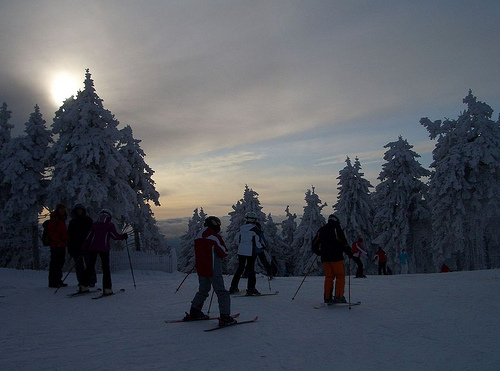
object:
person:
[305, 212, 364, 310]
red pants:
[320, 261, 347, 304]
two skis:
[314, 298, 364, 309]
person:
[180, 214, 240, 335]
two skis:
[165, 310, 258, 333]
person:
[70, 206, 139, 301]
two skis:
[67, 285, 126, 302]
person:
[227, 210, 282, 299]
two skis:
[227, 286, 280, 299]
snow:
[368, 276, 498, 371]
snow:
[33, 64, 147, 205]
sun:
[42, 69, 85, 107]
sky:
[145, 1, 375, 156]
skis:
[309, 301, 364, 310]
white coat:
[229, 222, 264, 257]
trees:
[287, 182, 331, 281]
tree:
[41, 67, 158, 273]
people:
[35, 197, 394, 335]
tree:
[413, 89, 498, 275]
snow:
[420, 89, 500, 270]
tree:
[365, 131, 430, 277]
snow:
[371, 134, 430, 276]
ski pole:
[346, 253, 354, 310]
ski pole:
[290, 255, 321, 302]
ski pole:
[175, 262, 197, 292]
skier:
[161, 214, 263, 338]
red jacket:
[183, 226, 231, 283]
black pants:
[225, 254, 259, 296]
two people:
[37, 202, 96, 298]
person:
[395, 248, 414, 275]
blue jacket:
[397, 248, 410, 264]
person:
[350, 237, 369, 280]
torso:
[440, 261, 451, 274]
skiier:
[440, 263, 450, 272]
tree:
[295, 184, 330, 278]